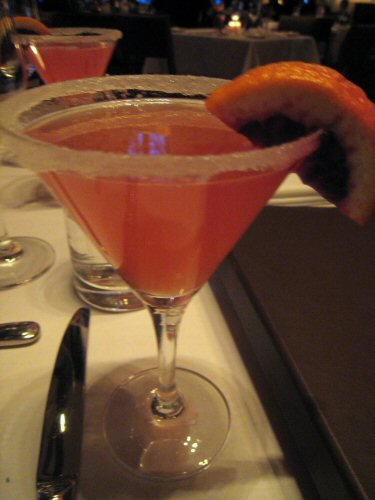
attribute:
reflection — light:
[53, 405, 70, 434]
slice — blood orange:
[203, 59, 362, 225]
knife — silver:
[33, 302, 90, 498]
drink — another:
[10, 25, 125, 140]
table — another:
[168, 22, 321, 88]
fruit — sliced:
[201, 59, 362, 228]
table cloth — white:
[1, 158, 348, 498]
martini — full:
[1, 70, 326, 485]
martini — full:
[12, 23, 127, 99]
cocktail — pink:
[29, 105, 294, 310]